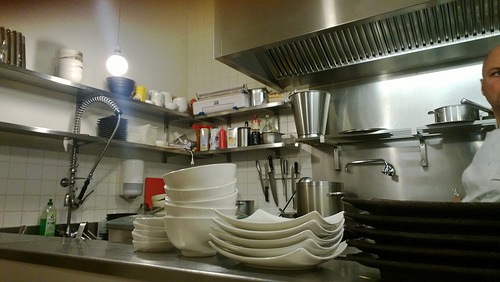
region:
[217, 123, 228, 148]
a red ketchup bottle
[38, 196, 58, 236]
green dish washing liquid in a clear bottle with a green top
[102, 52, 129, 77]
an illuminated light hanging from the ceiling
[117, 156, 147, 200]
a white soap dispenser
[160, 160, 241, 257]
white bowls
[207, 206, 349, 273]
white plates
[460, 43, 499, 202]
a chef in a white coat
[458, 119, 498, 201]
a white coat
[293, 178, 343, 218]
a silver pot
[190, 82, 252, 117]
a white plastic wrap dispenser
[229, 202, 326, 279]
stack of curved white plates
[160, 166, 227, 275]
stack of white bowls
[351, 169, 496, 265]
stack of brown plates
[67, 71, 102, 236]
tall stainless faucet over sink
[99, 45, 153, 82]
light fixture hanging from ceiling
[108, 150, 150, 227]
soap dispenser on wall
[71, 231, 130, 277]
stainless steel counter top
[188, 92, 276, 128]
small electronic on stainless shelf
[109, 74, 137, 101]
blue bowls stacked on stainless shelf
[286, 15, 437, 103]
stainless steel vent over stove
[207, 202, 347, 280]
pile of white plates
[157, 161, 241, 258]
pile of white bowls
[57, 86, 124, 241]
commercial sink and faucet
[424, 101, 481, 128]
a metal pot on the shelf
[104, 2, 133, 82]
white light hanging from the ceiling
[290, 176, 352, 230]
large metal pot on the stove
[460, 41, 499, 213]
chef with a white uniform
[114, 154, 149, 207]
white and gray soap dispenser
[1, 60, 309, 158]
silver, metal shelves on the wall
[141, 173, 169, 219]
red cutting board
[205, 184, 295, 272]
Stack of square plates.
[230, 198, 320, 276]
Stack of white plates.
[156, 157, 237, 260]
Stack of large bowls.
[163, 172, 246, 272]
Stack of white bowls.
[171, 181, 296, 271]
Stack of bowls next to stack of plates.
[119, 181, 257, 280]
Stacks of dishes on counter top.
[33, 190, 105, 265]
Green dish soap near sink.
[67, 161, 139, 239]
Silver hose on dish sink faucet.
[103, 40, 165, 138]
Circular light hanging down.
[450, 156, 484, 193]
Person wearing white shirt.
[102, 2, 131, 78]
light bulb dangling from cord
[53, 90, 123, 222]
commercial dish washing faucet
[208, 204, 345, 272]
stack of clean curved plates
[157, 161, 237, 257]
stack of clean white bowls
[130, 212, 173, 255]
stack of clean white condiment bowls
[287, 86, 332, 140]
large steel pail on shelf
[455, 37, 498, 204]
man standing behind black plates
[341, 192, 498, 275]
stack of clean black plates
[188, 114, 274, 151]
shelf lined with condiments, spices, and oils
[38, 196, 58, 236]
bottle of green dish soap